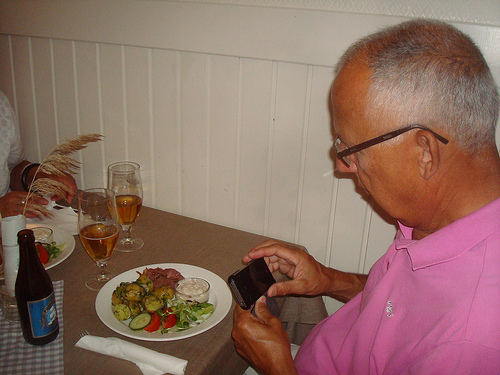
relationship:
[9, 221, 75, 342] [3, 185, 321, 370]
bottle on table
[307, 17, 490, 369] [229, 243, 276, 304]
man holding digital camera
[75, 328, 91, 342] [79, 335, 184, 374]
utensils inside napkin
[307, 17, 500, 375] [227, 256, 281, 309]
man looking cell phone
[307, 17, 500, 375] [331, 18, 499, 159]
man has hair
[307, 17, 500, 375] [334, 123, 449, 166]
man wearing glasses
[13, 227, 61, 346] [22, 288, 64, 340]
beer with blue label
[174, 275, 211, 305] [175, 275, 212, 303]
glass bowl in a dressing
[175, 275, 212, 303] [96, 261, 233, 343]
dressing on a plate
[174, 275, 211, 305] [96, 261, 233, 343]
glass bowl on a plate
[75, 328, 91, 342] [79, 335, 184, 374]
utensils rolled in a napkin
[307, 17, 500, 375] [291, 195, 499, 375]
man wearing polo shirt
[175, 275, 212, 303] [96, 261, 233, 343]
dressing on plate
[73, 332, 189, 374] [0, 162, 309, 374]
napkin on table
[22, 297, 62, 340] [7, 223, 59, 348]
blue label on bottle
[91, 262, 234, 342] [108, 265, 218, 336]
white plate with salad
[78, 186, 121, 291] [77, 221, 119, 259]
glass with beer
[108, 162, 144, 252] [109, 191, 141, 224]
glass with beer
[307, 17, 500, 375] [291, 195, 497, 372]
man in polo shirt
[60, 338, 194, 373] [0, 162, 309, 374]
rolled napkin on table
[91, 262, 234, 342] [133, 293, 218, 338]
white plate with salad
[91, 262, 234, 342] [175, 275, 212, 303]
white plate with dressing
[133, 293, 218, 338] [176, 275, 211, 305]
salad in glass bowl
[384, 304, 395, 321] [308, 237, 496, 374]
logo on shirt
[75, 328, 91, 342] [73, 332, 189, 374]
utensils wrapped in napkin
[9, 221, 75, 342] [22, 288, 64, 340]
bottle has blue label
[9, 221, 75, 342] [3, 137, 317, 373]
bottle on table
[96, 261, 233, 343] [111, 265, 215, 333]
plate of food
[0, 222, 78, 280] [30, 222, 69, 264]
plate of food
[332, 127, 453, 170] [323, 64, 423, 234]
glasses on man's face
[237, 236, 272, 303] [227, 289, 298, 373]
cell phone in hand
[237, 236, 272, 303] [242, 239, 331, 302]
cell phone in hand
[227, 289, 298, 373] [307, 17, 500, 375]
hand of man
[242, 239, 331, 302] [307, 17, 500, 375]
hand of man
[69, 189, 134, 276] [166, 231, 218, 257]
glasses on table